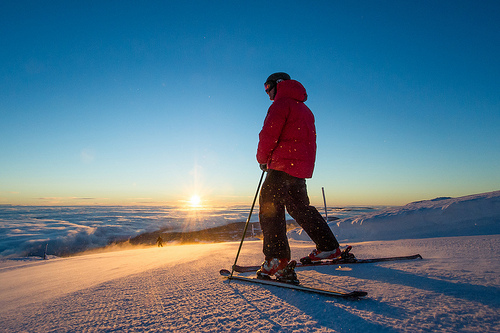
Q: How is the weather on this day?
A: It is clear.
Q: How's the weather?
A: It is clear.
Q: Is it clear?
A: Yes, it is clear.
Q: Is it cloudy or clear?
A: It is clear.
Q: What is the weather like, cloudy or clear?
A: It is clear.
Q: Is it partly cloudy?
A: No, it is clear.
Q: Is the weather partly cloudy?
A: No, it is clear.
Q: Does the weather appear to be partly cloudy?
A: No, it is clear.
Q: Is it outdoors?
A: Yes, it is outdoors.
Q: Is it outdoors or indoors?
A: It is outdoors.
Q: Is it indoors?
A: No, it is outdoors.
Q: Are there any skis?
A: Yes, there are skis.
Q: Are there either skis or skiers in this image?
A: Yes, there are skis.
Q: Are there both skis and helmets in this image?
A: Yes, there are both skis and a helmet.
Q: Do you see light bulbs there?
A: No, there are no light bulbs.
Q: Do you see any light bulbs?
A: No, there are no light bulbs.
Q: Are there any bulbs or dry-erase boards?
A: No, there are no bulbs or dry-erase boards.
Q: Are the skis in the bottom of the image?
A: Yes, the skis are in the bottom of the image.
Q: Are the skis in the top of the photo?
A: No, the skis are in the bottom of the image.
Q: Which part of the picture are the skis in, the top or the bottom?
A: The skis are in the bottom of the image.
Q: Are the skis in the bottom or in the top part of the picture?
A: The skis are in the bottom of the image.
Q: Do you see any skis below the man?
A: Yes, there are skis below the man.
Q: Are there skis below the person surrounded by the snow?
A: Yes, there are skis below the man.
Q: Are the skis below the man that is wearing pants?
A: Yes, the skis are below the man.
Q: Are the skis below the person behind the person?
A: Yes, the skis are below the man.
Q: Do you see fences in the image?
A: No, there are no fences.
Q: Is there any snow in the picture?
A: Yes, there is snow.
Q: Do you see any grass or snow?
A: Yes, there is snow.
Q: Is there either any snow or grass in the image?
A: Yes, there is snow.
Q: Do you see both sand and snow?
A: No, there is snow but no sand.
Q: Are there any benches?
A: No, there are no benches.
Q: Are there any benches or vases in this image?
A: No, there are no benches or vases.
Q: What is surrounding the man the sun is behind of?
A: The snow is surrounding the man.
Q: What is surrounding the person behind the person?
A: The snow is surrounding the man.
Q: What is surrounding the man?
A: The snow is surrounding the man.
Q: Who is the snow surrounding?
A: The snow is surrounding the man.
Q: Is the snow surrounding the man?
A: Yes, the snow is surrounding the man.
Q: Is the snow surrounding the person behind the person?
A: Yes, the snow is surrounding the man.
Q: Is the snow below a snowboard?
A: No, the snow is below the man.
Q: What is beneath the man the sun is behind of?
A: The snow is beneath the man.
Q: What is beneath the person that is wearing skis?
A: The snow is beneath the man.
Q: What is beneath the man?
A: The snow is beneath the man.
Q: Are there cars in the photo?
A: No, there are no cars.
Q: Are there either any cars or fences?
A: No, there are no cars or fences.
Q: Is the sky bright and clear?
A: Yes, the sky is bright and clear.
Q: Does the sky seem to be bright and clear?
A: Yes, the sky is bright and clear.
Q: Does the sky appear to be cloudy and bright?
A: No, the sky is bright but clear.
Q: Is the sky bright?
A: Yes, the sky is bright.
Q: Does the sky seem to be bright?
A: Yes, the sky is bright.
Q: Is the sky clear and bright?
A: Yes, the sky is clear and bright.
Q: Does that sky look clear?
A: Yes, the sky is clear.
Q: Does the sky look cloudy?
A: No, the sky is clear.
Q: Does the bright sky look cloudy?
A: No, the sky is clear.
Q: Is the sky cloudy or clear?
A: The sky is clear.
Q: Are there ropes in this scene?
A: No, there are no ropes.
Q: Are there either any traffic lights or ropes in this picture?
A: No, there are no ropes or traffic lights.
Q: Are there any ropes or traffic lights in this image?
A: No, there are no ropes or traffic lights.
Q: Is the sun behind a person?
A: Yes, the sun is behind a person.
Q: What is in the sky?
A: The sun is in the sky.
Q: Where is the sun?
A: The sun is in the sky.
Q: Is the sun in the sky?
A: Yes, the sun is in the sky.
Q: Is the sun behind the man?
A: Yes, the sun is behind the man.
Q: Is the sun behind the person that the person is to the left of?
A: Yes, the sun is behind the man.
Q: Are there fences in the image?
A: No, there are no fences.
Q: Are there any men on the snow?
A: Yes, there is a man on the snow.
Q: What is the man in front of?
A: The man is in front of the sun.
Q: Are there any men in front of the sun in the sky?
A: Yes, there is a man in front of the sun.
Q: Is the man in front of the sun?
A: Yes, the man is in front of the sun.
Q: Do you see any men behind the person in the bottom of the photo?
A: Yes, there is a man behind the person.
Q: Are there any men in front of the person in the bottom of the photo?
A: No, the man is behind the person.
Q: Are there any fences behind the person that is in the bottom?
A: No, there is a man behind the person.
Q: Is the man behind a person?
A: Yes, the man is behind a person.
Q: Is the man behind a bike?
A: No, the man is behind a person.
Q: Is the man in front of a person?
A: No, the man is behind a person.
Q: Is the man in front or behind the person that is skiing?
A: The man is behind the person.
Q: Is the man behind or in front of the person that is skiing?
A: The man is behind the person.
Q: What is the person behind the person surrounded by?
A: The man is surrounded by the snow.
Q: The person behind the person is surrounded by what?
A: The man is surrounded by the snow.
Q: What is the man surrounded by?
A: The man is surrounded by the snow.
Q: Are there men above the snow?
A: Yes, there is a man above the snow.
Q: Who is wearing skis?
A: The man is wearing skis.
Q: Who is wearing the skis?
A: The man is wearing skis.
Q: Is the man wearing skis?
A: Yes, the man is wearing skis.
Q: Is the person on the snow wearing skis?
A: Yes, the man is wearing skis.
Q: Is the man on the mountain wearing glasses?
A: No, the man is wearing skis.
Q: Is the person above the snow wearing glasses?
A: No, the man is wearing skis.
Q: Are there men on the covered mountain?
A: Yes, there is a man on the mountain.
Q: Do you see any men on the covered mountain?
A: Yes, there is a man on the mountain.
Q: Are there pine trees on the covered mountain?
A: No, there is a man on the mountain.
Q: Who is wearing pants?
A: The man is wearing pants.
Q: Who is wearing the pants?
A: The man is wearing pants.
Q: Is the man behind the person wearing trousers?
A: Yes, the man is wearing trousers.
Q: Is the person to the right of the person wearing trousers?
A: Yes, the man is wearing trousers.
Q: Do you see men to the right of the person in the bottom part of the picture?
A: Yes, there is a man to the right of the person.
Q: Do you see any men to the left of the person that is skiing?
A: No, the man is to the right of the person.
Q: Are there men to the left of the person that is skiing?
A: No, the man is to the right of the person.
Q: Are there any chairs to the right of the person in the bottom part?
A: No, there is a man to the right of the person.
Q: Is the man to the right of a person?
A: Yes, the man is to the right of a person.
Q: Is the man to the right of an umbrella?
A: No, the man is to the right of a person.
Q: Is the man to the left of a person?
A: No, the man is to the right of a person.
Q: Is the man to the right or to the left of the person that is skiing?
A: The man is to the right of the person.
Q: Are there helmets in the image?
A: Yes, there is a helmet.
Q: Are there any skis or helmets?
A: Yes, there is a helmet.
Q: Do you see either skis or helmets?
A: Yes, there is a helmet.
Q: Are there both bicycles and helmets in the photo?
A: No, there is a helmet but no bikes.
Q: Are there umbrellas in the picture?
A: No, there are no umbrellas.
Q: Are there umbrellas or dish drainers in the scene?
A: No, there are no umbrellas or dish drainers.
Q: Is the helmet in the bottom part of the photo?
A: No, the helmet is in the top of the image.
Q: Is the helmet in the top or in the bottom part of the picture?
A: The helmet is in the top of the image.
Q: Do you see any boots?
A: Yes, there are boots.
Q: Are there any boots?
A: Yes, there are boots.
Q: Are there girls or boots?
A: Yes, there are boots.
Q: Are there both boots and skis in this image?
A: Yes, there are both boots and skis.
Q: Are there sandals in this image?
A: No, there are no sandals.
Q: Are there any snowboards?
A: No, there are no snowboards.